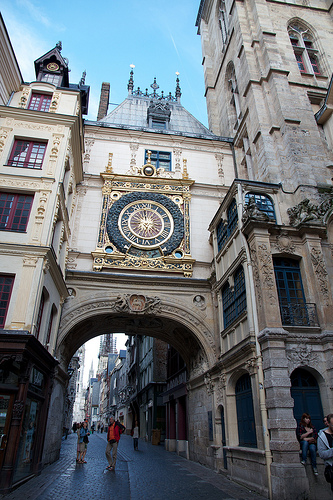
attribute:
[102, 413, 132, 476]
man — standing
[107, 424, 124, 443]
shirt — orange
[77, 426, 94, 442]
shirt — brown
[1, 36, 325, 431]
building — tall, gray, ornate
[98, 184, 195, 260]
clock — large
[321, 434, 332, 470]
shirt — black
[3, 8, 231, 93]
sky — blue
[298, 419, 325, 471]
woman — sitting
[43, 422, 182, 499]
road — black, paved, bricked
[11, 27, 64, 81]
clouds — white, thin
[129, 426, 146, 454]
person — walking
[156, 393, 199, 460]
doors — red